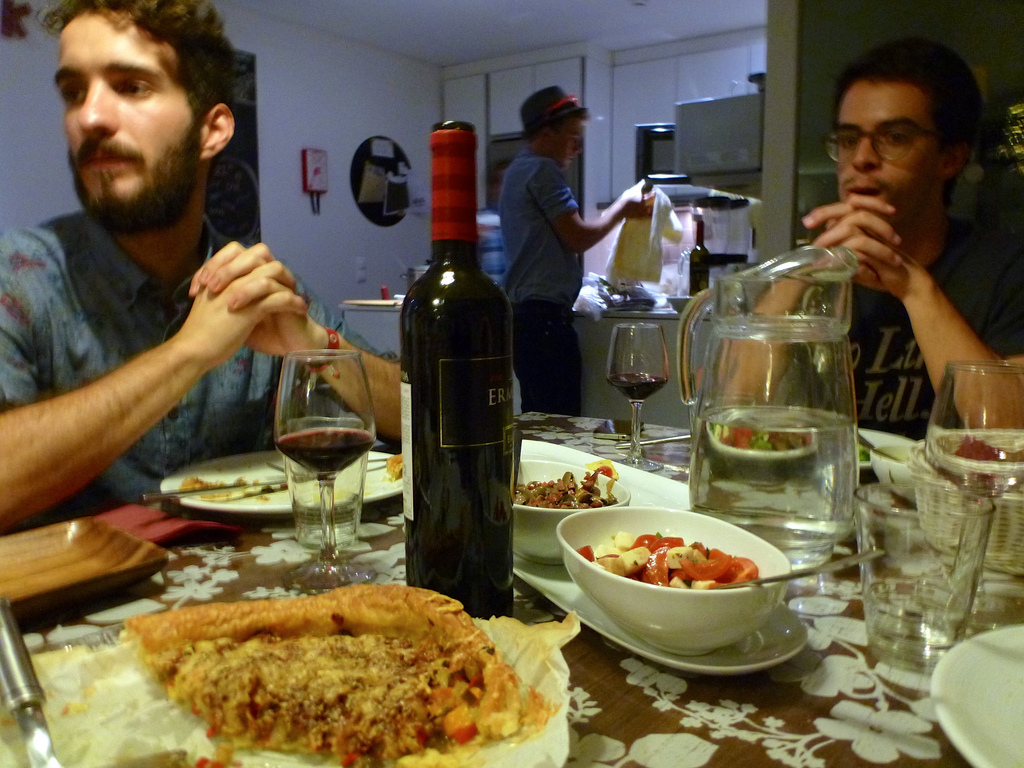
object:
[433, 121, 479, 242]
top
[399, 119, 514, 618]
bottle